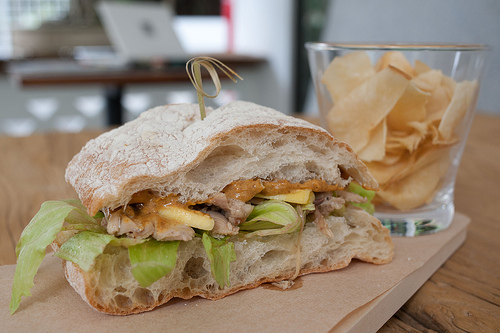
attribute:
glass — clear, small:
[304, 42, 493, 236]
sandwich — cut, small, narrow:
[9, 100, 397, 317]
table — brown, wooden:
[0, 110, 499, 332]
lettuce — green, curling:
[127, 238, 180, 287]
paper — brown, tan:
[2, 210, 470, 332]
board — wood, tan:
[333, 224, 468, 333]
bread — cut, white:
[61, 205, 395, 317]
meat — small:
[106, 205, 196, 242]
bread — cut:
[63, 99, 383, 216]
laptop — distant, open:
[96, 2, 266, 69]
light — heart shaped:
[25, 98, 59, 122]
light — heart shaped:
[76, 94, 105, 116]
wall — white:
[2, 2, 297, 134]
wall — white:
[305, 2, 500, 113]